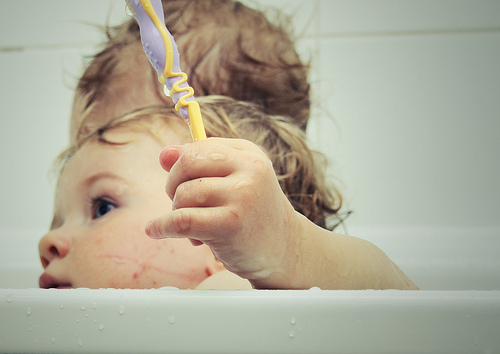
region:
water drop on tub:
[284, 312, 301, 327]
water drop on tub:
[166, 302, 175, 335]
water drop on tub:
[109, 299, 132, 315]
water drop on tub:
[76, 299, 100, 311]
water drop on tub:
[92, 318, 112, 335]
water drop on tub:
[22, 304, 47, 335]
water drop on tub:
[309, 278, 330, 308]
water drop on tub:
[167, 279, 182, 295]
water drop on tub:
[51, 292, 74, 323]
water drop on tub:
[39, 324, 61, 345]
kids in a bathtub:
[76, 18, 403, 353]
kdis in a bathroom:
[87, 58, 496, 351]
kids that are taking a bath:
[66, 36, 401, 339]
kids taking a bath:
[8, 29, 482, 319]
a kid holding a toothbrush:
[65, 86, 432, 327]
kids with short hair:
[80, 48, 394, 263]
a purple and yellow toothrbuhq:
[89, 26, 324, 286]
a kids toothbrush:
[117, 71, 395, 346]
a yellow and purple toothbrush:
[119, 51, 279, 240]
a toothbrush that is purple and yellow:
[112, 28, 382, 254]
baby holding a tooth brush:
[158, 80, 226, 198]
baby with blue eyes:
[86, 192, 121, 223]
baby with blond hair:
[82, 100, 350, 232]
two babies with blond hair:
[61, 44, 353, 214]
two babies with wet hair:
[82, 38, 305, 190]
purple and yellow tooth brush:
[130, 13, 212, 154]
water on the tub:
[21, 275, 361, 331]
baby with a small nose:
[33, 224, 78, 261]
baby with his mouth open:
[30, 263, 80, 295]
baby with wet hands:
[159, 118, 294, 238]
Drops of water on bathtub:
[18, 297, 123, 343]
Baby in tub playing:
[26, 71, 407, 284]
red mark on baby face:
[100, 247, 166, 279]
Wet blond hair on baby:
[265, 105, 313, 167]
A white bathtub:
[346, 305, 451, 346]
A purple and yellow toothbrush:
[132, 13, 199, 108]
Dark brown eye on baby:
[82, 195, 122, 222]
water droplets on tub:
[280, 312, 325, 349]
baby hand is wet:
[136, 132, 276, 242]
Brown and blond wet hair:
[267, 113, 332, 165]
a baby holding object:
[128, 26, 225, 132]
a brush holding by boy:
[120, 10, 221, 136]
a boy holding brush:
[112, 5, 279, 255]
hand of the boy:
[130, 146, 302, 298]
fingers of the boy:
[156, 198, 193, 253]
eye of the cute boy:
[76, 169, 138, 249]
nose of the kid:
[26, 225, 105, 272]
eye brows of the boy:
[75, 166, 140, 187]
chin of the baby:
[96, 225, 203, 307]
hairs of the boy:
[178, 27, 385, 157]